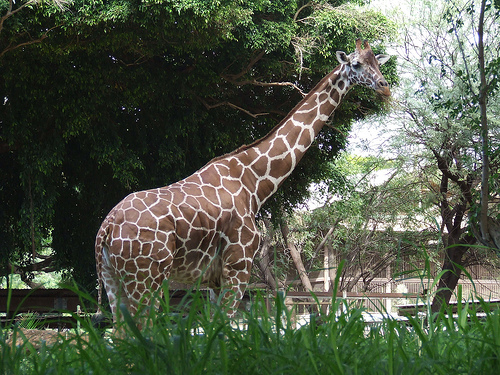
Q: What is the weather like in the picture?
A: It is cloudy.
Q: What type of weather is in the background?
A: It is cloudy.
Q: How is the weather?
A: It is cloudy.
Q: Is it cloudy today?
A: Yes, it is cloudy.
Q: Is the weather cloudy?
A: Yes, it is cloudy.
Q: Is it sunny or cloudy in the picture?
A: It is cloudy.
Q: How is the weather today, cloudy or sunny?
A: It is cloudy.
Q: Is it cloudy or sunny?
A: It is cloudy.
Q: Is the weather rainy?
A: No, it is cloudy.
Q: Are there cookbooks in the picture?
A: No, there are no cookbooks.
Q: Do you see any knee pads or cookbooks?
A: No, there are no cookbooks or knee pads.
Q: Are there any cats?
A: No, there are no cats.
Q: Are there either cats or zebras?
A: No, there are no cats or zebras.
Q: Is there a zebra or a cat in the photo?
A: No, there are no cats or zebras.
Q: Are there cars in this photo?
A: No, there are no cars.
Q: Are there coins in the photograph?
A: No, there are no coins.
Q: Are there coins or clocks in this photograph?
A: No, there are no coins or clocks.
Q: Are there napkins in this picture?
A: No, there are no napkins.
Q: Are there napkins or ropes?
A: No, there are no napkins or ropes.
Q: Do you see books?
A: No, there are no books.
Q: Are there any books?
A: No, there are no books.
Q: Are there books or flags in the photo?
A: No, there are no books or flags.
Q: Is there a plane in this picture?
A: No, there are no airplanes.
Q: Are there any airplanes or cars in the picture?
A: No, there are no airplanes or cars.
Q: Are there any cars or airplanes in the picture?
A: No, there are no airplanes or cars.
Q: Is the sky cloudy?
A: Yes, the sky is cloudy.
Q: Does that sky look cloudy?
A: Yes, the sky is cloudy.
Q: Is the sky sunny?
A: No, the sky is cloudy.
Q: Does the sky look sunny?
A: No, the sky is cloudy.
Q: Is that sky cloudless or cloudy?
A: The sky is cloudy.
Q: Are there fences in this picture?
A: Yes, there is a fence.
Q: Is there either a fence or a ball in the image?
A: Yes, there is a fence.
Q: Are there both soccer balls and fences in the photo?
A: No, there is a fence but no soccer balls.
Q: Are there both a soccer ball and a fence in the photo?
A: No, there is a fence but no soccer balls.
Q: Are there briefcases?
A: No, there are no briefcases.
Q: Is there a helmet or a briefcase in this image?
A: No, there are no briefcases or helmets.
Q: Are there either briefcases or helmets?
A: No, there are no briefcases or helmets.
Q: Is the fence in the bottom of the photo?
A: Yes, the fence is in the bottom of the image.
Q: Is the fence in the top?
A: No, the fence is in the bottom of the image.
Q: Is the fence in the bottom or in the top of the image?
A: The fence is in the bottom of the image.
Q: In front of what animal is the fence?
A: The fence is in front of the giraffe.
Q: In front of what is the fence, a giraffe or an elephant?
A: The fence is in front of a giraffe.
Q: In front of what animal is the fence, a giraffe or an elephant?
A: The fence is in front of a giraffe.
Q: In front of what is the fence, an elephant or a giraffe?
A: The fence is in front of a giraffe.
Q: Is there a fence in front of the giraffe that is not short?
A: Yes, there is a fence in front of the giraffe.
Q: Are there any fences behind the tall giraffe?
A: No, the fence is in front of the giraffe.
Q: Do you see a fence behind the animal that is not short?
A: No, the fence is in front of the giraffe.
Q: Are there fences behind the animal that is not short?
A: No, the fence is in front of the giraffe.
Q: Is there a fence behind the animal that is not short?
A: No, the fence is in front of the giraffe.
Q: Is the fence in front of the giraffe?
A: Yes, the fence is in front of the giraffe.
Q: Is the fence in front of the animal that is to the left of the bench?
A: Yes, the fence is in front of the giraffe.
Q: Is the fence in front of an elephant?
A: No, the fence is in front of the giraffe.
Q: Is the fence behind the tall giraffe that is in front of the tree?
A: No, the fence is in front of the giraffe.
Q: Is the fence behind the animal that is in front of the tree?
A: No, the fence is in front of the giraffe.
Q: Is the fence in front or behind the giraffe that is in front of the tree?
A: The fence is in front of the giraffe.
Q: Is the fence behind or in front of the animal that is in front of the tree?
A: The fence is in front of the giraffe.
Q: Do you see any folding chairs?
A: No, there are no folding chairs.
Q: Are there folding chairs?
A: No, there are no folding chairs.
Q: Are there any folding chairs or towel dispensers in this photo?
A: No, there are no folding chairs or towel dispensers.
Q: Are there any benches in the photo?
A: Yes, there is a bench.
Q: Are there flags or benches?
A: Yes, there is a bench.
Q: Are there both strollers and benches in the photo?
A: No, there is a bench but no strollers.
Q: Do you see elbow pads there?
A: No, there are no elbow pads.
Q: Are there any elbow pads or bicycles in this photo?
A: No, there are no elbow pads or bicycles.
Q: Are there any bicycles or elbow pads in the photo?
A: No, there are no elbow pads or bicycles.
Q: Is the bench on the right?
A: Yes, the bench is on the right of the image.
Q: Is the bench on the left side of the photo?
A: No, the bench is on the right of the image.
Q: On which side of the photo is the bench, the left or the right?
A: The bench is on the right of the image.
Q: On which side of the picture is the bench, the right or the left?
A: The bench is on the right of the image.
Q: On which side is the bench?
A: The bench is on the right of the image.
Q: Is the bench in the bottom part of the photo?
A: Yes, the bench is in the bottom of the image.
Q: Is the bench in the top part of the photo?
A: No, the bench is in the bottom of the image.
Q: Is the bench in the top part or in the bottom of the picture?
A: The bench is in the bottom of the image.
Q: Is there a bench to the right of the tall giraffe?
A: Yes, there is a bench to the right of the giraffe.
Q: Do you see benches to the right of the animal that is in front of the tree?
A: Yes, there is a bench to the right of the giraffe.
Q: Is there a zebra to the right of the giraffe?
A: No, there is a bench to the right of the giraffe.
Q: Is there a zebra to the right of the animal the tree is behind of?
A: No, there is a bench to the right of the giraffe.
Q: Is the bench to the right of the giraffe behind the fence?
A: Yes, the bench is to the right of the giraffe.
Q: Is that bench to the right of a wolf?
A: No, the bench is to the right of the giraffe.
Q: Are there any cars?
A: No, there are no cars.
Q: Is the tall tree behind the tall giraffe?
A: Yes, the tree is behind the giraffe.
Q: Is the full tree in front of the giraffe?
A: No, the tree is behind the giraffe.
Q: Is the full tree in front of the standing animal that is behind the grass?
A: No, the tree is behind the giraffe.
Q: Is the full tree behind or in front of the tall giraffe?
A: The tree is behind the giraffe.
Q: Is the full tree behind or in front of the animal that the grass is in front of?
A: The tree is behind the giraffe.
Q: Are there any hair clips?
A: No, there are no hair clips.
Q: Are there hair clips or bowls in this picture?
A: No, there are no hair clips or bowls.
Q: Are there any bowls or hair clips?
A: No, there are no hair clips or bowls.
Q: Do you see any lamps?
A: No, there are no lamps.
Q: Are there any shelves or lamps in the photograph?
A: No, there are no lamps or shelves.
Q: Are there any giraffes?
A: Yes, there is a giraffe.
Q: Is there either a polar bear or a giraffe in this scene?
A: Yes, there is a giraffe.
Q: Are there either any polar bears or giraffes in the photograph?
A: Yes, there is a giraffe.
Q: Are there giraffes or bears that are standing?
A: Yes, the giraffe is standing.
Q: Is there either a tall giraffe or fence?
A: Yes, there is a tall giraffe.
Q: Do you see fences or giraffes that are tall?
A: Yes, the giraffe is tall.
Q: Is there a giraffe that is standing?
A: Yes, there is a giraffe that is standing.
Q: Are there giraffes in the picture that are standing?
A: Yes, there is a giraffe that is standing.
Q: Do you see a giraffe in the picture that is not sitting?
A: Yes, there is a giraffe that is standing .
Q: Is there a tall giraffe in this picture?
A: Yes, there is a tall giraffe.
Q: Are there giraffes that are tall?
A: Yes, there is a giraffe that is tall.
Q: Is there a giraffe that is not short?
A: Yes, there is a tall giraffe.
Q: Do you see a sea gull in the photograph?
A: No, there are no seagulls.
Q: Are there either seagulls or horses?
A: No, there are no seagulls or horses.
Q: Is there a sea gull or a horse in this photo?
A: No, there are no seagulls or horses.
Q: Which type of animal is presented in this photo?
A: The animal is a giraffe.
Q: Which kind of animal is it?
A: The animal is a giraffe.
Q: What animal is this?
A: This is a giraffe.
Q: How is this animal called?
A: This is a giraffe.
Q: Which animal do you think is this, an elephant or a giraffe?
A: This is a giraffe.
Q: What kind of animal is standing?
A: The animal is a giraffe.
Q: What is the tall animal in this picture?
A: The animal is a giraffe.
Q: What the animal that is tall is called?
A: The animal is a giraffe.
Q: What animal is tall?
A: The animal is a giraffe.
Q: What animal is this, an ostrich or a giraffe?
A: This is a giraffe.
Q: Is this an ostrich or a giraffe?
A: This is a giraffe.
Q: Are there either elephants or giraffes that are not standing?
A: No, there is a giraffe but it is standing.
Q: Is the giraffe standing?
A: Yes, the giraffe is standing.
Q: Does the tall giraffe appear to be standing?
A: Yes, the giraffe is standing.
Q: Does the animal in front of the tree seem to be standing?
A: Yes, the giraffe is standing.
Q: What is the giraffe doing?
A: The giraffe is standing.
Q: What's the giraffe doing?
A: The giraffe is standing.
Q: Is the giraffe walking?
A: No, the giraffe is standing.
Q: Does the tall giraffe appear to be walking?
A: No, the giraffe is standing.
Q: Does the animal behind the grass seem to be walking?
A: No, the giraffe is standing.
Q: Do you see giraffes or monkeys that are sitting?
A: No, there is a giraffe but it is standing.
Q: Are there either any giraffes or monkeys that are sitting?
A: No, there is a giraffe but it is standing.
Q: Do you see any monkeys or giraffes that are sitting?
A: No, there is a giraffe but it is standing.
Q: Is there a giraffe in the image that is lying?
A: No, there is a giraffe but it is standing.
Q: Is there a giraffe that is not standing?
A: No, there is a giraffe but it is standing.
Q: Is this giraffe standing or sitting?
A: The giraffe is standing.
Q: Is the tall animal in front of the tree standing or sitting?
A: The giraffe is standing.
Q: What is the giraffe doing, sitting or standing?
A: The giraffe is standing.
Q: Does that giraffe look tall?
A: Yes, the giraffe is tall.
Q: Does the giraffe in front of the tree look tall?
A: Yes, the giraffe is tall.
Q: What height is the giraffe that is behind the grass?
A: The giraffe is tall.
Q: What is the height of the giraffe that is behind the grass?
A: The giraffe is tall.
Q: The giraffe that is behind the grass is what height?
A: The giraffe is tall.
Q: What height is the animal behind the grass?
A: The giraffe is tall.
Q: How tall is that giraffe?
A: The giraffe is tall.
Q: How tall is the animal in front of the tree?
A: The giraffe is tall.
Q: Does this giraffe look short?
A: No, the giraffe is tall.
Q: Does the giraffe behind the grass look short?
A: No, the giraffe is tall.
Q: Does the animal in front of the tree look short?
A: No, the giraffe is tall.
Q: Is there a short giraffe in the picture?
A: No, there is a giraffe but it is tall.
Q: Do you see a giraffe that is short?
A: No, there is a giraffe but it is tall.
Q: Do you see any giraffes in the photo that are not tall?
A: No, there is a giraffe but it is tall.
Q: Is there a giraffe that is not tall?
A: No, there is a giraffe but it is tall.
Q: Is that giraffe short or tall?
A: The giraffe is tall.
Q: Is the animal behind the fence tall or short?
A: The giraffe is tall.